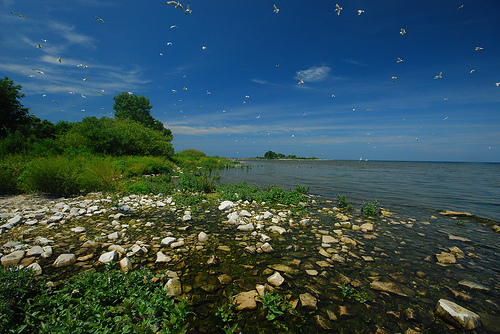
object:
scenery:
[0, 0, 500, 332]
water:
[248, 167, 315, 182]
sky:
[0, 0, 500, 162]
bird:
[334, 3, 343, 16]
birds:
[469, 69, 475, 73]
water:
[373, 159, 499, 194]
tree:
[112, 91, 173, 135]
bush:
[18, 154, 128, 199]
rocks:
[433, 298, 482, 331]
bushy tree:
[0, 75, 36, 138]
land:
[0, 191, 174, 209]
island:
[256, 150, 319, 159]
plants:
[229, 289, 265, 310]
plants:
[218, 201, 234, 211]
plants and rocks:
[0, 187, 499, 333]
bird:
[273, 4, 280, 13]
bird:
[357, 10, 364, 16]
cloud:
[293, 66, 331, 89]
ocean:
[239, 161, 499, 217]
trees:
[52, 115, 176, 159]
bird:
[399, 28, 406, 36]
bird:
[396, 57, 403, 63]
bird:
[433, 70, 442, 80]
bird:
[475, 47, 483, 52]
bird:
[391, 76, 397, 82]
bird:
[166, 0, 189, 15]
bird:
[94, 16, 106, 24]